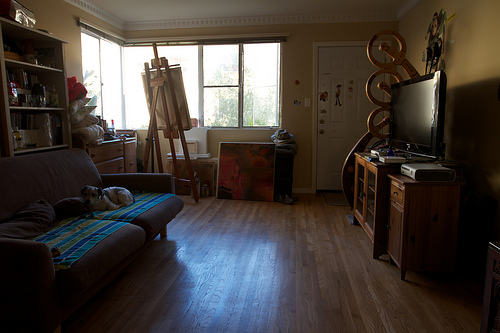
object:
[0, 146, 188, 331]
couch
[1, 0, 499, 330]
living room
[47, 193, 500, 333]
floor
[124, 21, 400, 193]
wall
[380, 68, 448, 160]
tv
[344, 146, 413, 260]
stand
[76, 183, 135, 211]
dog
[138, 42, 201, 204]
art easel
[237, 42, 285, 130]
windows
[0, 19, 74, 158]
bookcase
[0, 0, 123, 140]
wall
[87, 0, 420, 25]
ceiling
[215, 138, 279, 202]
painting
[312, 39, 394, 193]
door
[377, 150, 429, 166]
game console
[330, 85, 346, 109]
stickers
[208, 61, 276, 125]
trees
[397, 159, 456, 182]
xbox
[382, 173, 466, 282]
cabinet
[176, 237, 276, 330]
sunlight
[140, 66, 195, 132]
canvas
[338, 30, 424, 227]
sculpture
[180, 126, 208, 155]
canvas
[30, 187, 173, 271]
cloth